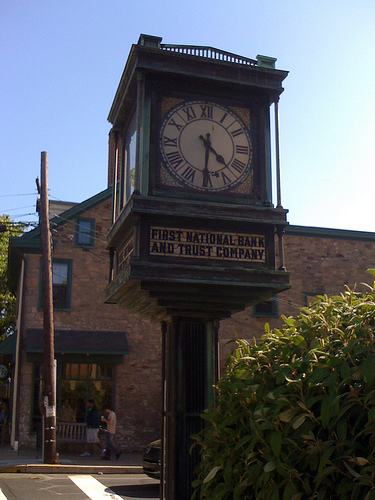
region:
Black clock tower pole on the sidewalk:
[102, 30, 293, 494]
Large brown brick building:
[5, 182, 373, 465]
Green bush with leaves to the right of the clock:
[184, 261, 371, 496]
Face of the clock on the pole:
[152, 92, 259, 200]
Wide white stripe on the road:
[61, 471, 123, 498]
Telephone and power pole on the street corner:
[32, 147, 59, 464]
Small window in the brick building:
[71, 212, 95, 252]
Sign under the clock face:
[144, 218, 273, 265]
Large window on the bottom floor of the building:
[19, 327, 128, 468]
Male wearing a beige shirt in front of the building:
[96, 400, 120, 463]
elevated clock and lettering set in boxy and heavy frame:
[103, 30, 288, 317]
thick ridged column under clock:
[151, 315, 226, 495]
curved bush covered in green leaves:
[202, 287, 367, 492]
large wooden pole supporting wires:
[3, 150, 108, 467]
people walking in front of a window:
[75, 350, 121, 460]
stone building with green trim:
[11, 184, 363, 464]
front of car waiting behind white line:
[60, 420, 157, 495]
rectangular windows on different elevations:
[31, 211, 91, 309]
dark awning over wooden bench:
[16, 317, 130, 458]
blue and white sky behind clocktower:
[4, 3, 371, 231]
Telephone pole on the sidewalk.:
[36, 147, 60, 467]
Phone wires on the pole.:
[53, 215, 114, 254]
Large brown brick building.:
[290, 246, 353, 287]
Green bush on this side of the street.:
[249, 301, 363, 482]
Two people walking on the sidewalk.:
[74, 393, 129, 464]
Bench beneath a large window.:
[57, 423, 88, 451]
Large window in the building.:
[51, 361, 118, 429]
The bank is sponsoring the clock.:
[141, 226, 285, 264]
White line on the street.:
[59, 477, 129, 498]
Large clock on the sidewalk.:
[111, 51, 291, 306]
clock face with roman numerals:
[157, 97, 262, 194]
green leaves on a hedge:
[230, 335, 350, 479]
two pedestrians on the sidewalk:
[70, 393, 133, 459]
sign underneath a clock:
[147, 226, 270, 264]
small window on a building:
[70, 211, 96, 250]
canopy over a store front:
[30, 323, 143, 365]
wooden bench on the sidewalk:
[35, 415, 126, 458]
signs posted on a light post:
[41, 391, 61, 422]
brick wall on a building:
[131, 353, 154, 414]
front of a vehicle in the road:
[140, 433, 164, 487]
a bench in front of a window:
[53, 418, 89, 448]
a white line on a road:
[69, 471, 122, 498]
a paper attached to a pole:
[44, 401, 57, 422]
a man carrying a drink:
[96, 402, 126, 459]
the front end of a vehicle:
[141, 433, 162, 478]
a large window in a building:
[39, 358, 117, 424]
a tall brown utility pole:
[37, 149, 59, 461]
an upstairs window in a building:
[69, 212, 99, 248]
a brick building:
[20, 196, 371, 452]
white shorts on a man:
[83, 426, 101, 446]